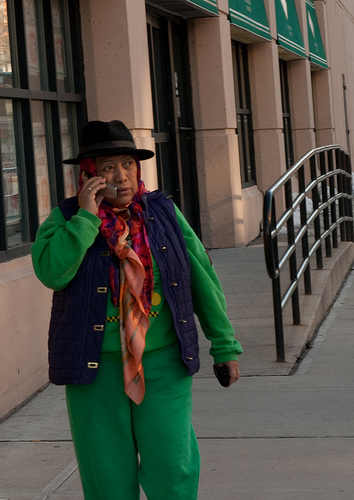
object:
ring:
[85, 186, 92, 190]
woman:
[30, 118, 244, 497]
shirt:
[30, 191, 243, 365]